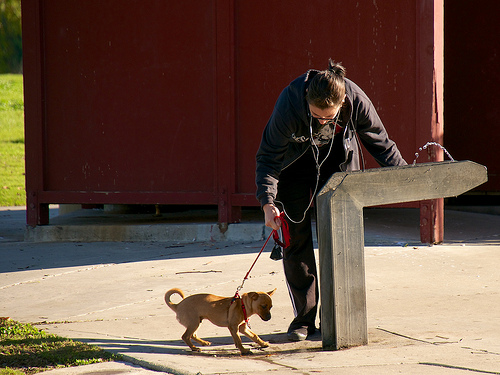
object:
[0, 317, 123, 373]
grass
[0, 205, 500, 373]
pavement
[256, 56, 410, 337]
woman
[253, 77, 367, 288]
woman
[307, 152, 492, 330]
waterfountain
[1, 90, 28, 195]
grass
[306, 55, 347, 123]
woman's head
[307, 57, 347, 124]
head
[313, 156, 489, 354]
post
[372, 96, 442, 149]
ground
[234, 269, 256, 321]
harness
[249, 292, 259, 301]
ear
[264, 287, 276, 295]
ear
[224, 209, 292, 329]
leash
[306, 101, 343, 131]
woman's face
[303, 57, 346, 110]
hair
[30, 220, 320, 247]
foundation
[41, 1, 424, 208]
wall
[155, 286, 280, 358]
dog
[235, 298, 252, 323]
collar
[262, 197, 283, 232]
hand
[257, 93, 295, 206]
arm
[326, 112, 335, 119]
eye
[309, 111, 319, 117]
eye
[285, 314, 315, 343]
foot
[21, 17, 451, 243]
building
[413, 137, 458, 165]
fountain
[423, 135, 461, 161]
water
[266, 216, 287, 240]
tie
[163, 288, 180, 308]
tail